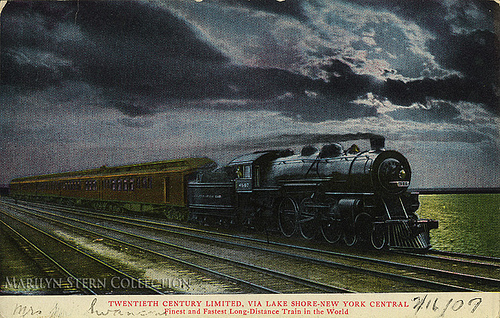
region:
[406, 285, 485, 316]
date in corner of postcard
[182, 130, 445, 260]
black train engine on track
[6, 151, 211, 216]
long brown passenger car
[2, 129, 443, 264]
train moving along track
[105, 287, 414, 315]
red wording on bottom of card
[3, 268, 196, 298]
white wording on card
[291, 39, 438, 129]
reflection of moonlight in distant clouds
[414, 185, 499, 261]
green field beyond train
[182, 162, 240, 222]
coal bin behind engine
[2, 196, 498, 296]
long narrow train tracks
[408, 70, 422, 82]
part of a cloud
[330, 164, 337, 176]
part of a train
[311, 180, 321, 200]
side of a train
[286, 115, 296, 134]
part of a cloud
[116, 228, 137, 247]
part of a rail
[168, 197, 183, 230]
edge of a rail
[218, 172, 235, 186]
side of a train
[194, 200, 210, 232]
edge of a rail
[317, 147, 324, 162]
part of an engine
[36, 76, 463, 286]
the painting is a train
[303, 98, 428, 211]
the smoke is black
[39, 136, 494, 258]
passenger cars are yellow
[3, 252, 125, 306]
marilyn stern is the name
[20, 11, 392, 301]
this is a postcard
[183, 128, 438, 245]
train engine is black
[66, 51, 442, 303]
the train is on tracks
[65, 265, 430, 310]
twentieth century limited was the line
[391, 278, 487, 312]
postcard dated 7/16/07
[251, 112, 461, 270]
the train has a cow catcher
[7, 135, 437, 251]
An old train on a cloudy day.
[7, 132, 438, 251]
Old train moving down the track.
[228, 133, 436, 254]
The front car of the train is black.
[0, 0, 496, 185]
The sky is dark and cloudy.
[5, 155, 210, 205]
The train cars are yellow.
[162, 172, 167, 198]
The first train car has a door for passengers.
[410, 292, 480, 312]
The date stamp on the photo.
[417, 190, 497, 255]
Field of grass behind the train.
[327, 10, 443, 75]
Hole in the clouds above the train.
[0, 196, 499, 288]
Multiple train tracks are present.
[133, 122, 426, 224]
this is a train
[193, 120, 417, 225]
the train is black in color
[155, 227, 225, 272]
these are the rails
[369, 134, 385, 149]
this is a chimney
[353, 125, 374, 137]
the smoke is from the chimney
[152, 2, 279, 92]
the clouds are above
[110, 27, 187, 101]
the clouds are grey in color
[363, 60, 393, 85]
the sun is setting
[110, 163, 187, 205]
these are the carriages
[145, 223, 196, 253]
the rails are in a line